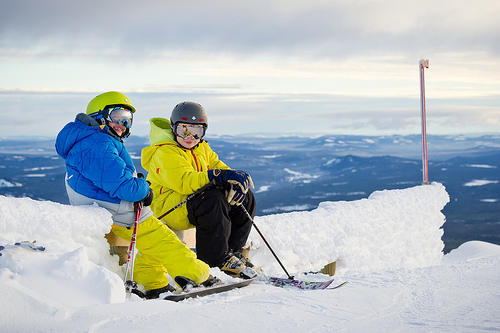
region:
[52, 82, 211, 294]
skier on snowy slope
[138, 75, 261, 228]
skier on snowy slope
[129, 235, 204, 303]
yellow pants on skier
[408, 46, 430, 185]
pole on ski slope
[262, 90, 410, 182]
mountains in the distance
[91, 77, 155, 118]
yellow helmet on man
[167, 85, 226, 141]
gray helmet on skier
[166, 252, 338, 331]
skis on snowy slope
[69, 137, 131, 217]
blue jacket on skier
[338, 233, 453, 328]
footprints in white snow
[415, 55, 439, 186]
some type of poll or marker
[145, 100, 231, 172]
a lady skier wearing a gray ski helmet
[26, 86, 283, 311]
2 ladies skiers set down on a snowbank snowbank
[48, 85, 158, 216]
ladies scare on the left wearing a blue ski jacket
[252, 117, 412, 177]
a mountain range in the distant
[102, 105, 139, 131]
mirrored sunglasses on the skier shields the sun's rays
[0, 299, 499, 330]
white fluffy snow underneath the skier speak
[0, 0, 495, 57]
purple and gray clouds are in the backdrop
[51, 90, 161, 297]
lady in the blue ski jacket rest her right arm against ski pole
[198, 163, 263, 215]
skier is wearing gloves thick in material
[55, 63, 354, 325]
two people on skis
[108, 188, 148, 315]
red and white ski poles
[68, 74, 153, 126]
a bright green helmet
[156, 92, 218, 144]
a gray and red helmet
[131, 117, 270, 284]
yellow jacket and black pants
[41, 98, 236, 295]
blue jacket and yellow pants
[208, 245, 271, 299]
yellow and black ski boots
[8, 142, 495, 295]
a mound of snow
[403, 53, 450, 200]
a red pole on the end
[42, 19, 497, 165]
white clouds in the sky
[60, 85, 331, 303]
People sitting in the snow.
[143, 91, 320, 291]
Person wearing skis on feet.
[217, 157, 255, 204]
The person is wearing gloves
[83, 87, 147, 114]
The person is wearing a yellow helmet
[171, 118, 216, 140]
Goggles over the face of person.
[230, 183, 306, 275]
Ski pole in the person hand.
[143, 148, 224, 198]
The jacket is yellow.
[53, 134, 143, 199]
Person wearing a blue jacket.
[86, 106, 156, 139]
The child is smiling.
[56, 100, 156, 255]
The child is sitting on the snow.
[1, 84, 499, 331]
Two skiiers sitting down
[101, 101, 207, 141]
A pair of goggles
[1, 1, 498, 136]
The sky is very cloudy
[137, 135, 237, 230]
A yellow ski jacket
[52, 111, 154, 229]
A blue and white jacket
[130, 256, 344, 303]
Skis are on the snow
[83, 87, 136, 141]
A helmet is green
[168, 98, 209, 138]
The helmet is gray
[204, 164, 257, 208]
A pair of gloves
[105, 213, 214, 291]
The pants are bright yellow